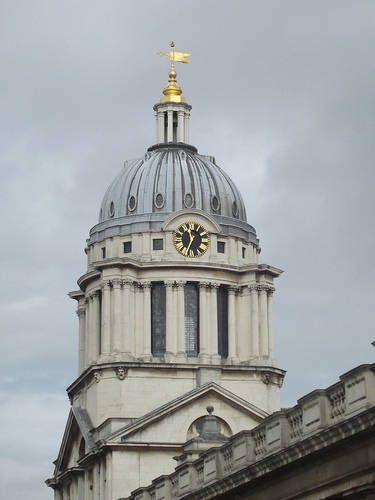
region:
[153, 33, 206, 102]
gold piece on top o building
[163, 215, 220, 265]
round gold clock on building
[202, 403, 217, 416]
small round ball on building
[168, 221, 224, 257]
clock with a black face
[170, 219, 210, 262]
clock with gold numbers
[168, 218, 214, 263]
clock with Roman numerals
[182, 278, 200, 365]
window high on the building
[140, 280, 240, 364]
three windows on the building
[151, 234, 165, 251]
small opening by the clock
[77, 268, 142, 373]
columns near the top of the building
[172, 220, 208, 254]
clock's hands are gold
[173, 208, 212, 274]
clock's hands are gold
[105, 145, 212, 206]
a gray dome shaped roof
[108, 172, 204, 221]
a gray dome shaped roof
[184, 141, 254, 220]
a gray dome shaped roof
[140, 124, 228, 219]
a gray dome shaped roof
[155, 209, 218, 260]
clock on side of building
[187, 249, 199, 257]
roman numeral on clock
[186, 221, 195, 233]
roman numeral on clock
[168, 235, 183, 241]
roman numeral on clock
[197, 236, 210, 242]
roman numeral on clock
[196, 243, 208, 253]
roman numeral on clock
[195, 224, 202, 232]
roman numeral on clock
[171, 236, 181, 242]
roman numeral on clock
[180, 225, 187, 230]
roman numeral on clock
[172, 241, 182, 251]
roman numeral on clock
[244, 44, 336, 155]
Sky is blue color.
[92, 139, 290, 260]
Tower is dome shape.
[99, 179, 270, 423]
Tower is white color.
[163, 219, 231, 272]
Clock is fixed to the tower.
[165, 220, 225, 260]
Clock is black and golden color.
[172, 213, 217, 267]
Numbers are in Roman letters.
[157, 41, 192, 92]
Flag on top of the tower.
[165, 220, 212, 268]
11.40 is the time shown.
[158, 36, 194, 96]
Flag is golden color.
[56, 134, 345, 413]
Day time picture.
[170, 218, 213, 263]
a clock in a tower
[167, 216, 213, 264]
a clock with black background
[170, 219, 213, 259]
clock has roman numerals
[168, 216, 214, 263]
handles of clock are yellow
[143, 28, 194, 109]
top of tower is gold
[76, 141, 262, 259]
dome of a tower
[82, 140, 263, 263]
dome is color tan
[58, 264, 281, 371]
columns around under a clock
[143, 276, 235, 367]
three long windows under a clock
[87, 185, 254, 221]
circles on dome